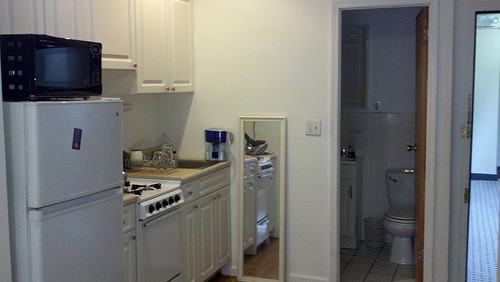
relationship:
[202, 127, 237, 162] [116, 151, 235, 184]
pitcher sitting on counter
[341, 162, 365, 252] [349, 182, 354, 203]
cabinet has knob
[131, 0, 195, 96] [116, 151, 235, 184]
cabinet above counter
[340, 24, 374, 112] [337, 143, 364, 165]
mirror above sink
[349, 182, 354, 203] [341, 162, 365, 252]
knob on cabinet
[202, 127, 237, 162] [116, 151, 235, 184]
pitcher on top of counter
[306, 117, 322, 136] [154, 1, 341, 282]
light switch mounted on wall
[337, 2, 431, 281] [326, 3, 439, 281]
bathroom has doorway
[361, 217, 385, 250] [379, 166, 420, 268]
wastebasket next to toilet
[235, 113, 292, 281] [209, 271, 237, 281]
mirror on floor